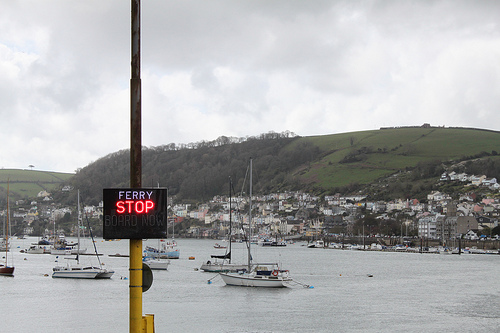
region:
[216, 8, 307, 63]
a bunch of grey clouds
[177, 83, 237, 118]
a bunch of white clouds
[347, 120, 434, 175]
a giant green hill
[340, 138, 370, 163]
a bunch of trees on a hill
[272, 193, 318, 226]
a group of large houses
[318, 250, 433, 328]
the water in a large sea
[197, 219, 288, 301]
a bunch of little boat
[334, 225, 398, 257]
a big brown pier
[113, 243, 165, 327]
a small yellow pole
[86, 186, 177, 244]
an electric ferry stop sign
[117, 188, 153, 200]
the bright blue word Ferry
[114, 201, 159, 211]
the red word stop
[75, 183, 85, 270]
the tall white mast of a sailboat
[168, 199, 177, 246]
a duck swimming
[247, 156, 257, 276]
a duck swimming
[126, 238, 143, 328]
the yellow bottom half of a pole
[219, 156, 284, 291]
the white sailboat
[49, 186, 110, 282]
a duck swimming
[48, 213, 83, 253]
a duck swimming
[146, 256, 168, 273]
a duck swimming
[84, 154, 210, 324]
a sign on a pole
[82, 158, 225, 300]
a sign on a metal pole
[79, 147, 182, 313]
a pole with a sign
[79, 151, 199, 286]
a metal pole with a sign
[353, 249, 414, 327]
a body of water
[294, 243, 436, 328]
a body of calm water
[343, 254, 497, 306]
a body of water that is calm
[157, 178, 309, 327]
boats in the water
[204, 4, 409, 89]
a sky with clouds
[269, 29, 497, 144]
a sky with white clouds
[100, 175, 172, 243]
a ferry sign with stop lit up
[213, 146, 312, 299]
a white sail boat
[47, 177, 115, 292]
a white sail boat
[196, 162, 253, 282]
a white sail boat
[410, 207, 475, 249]
a multi level building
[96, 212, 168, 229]
unlit board now letters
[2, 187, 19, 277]
a red sail boat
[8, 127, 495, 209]
a hilly country side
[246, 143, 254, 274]
a metal sail mast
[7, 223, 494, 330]
a body of water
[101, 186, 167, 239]
ferry traffic signal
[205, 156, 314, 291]
sailing boat double anchored in harbor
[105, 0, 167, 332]
ferry signal on yellow pole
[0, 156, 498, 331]
boats at anchor and at dock in harbor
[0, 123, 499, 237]
hills rising up from harbor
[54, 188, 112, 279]
sailing catamaran at anchor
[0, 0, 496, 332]
harbor at daytime with low hanging clouds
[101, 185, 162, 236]
ferry illuminated instructions sign STOP / BOARD NOW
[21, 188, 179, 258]
boats moored to log booms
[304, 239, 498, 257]
small boats at docks